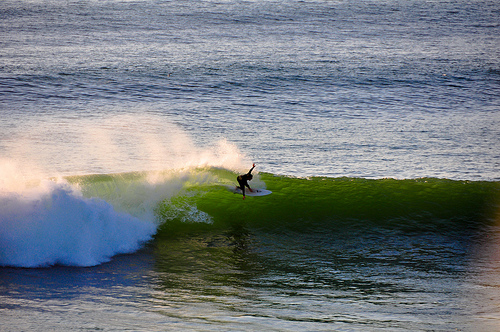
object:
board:
[228, 185, 273, 197]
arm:
[247, 167, 254, 174]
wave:
[0, 137, 268, 268]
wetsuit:
[237, 167, 255, 189]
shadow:
[205, 221, 255, 253]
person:
[235, 163, 255, 200]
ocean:
[0, 0, 500, 332]